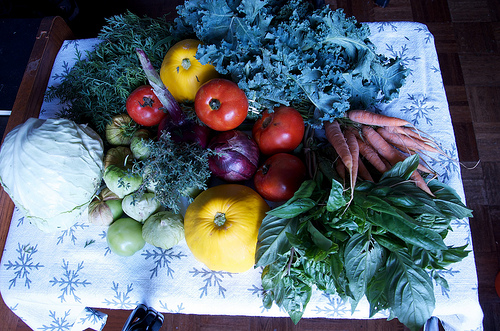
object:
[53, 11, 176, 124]
thyme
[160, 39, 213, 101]
squash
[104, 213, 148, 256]
tomato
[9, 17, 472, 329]
platter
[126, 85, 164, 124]
tomato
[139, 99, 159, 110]
stem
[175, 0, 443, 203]
carrots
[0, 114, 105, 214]
cabbage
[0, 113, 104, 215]
kale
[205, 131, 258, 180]
onion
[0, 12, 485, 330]
table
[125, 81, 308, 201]
tomatoes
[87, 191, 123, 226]
tomato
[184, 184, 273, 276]
squash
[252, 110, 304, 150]
tomato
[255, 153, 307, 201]
tomato